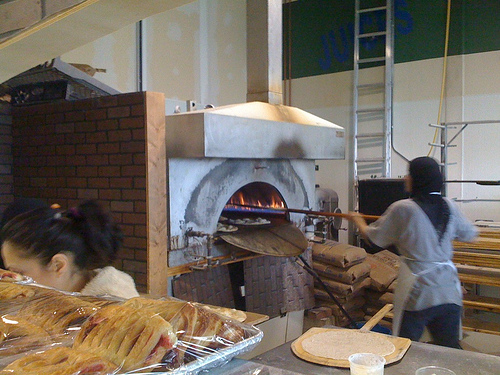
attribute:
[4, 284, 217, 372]
wrap — plastic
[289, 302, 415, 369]
tray — wooden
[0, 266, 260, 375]
pastries — wrapped, fresh, cherry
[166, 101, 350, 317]
oven — large, stone, brick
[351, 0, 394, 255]
ladder — tall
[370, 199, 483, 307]
shirt — grey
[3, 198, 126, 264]
hair — black, up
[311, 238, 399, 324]
flower — unopened, large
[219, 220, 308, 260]
door — open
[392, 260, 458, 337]
apron — white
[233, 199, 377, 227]
spatula — wooden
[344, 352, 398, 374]
cup — plastic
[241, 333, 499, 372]
countertop — grey